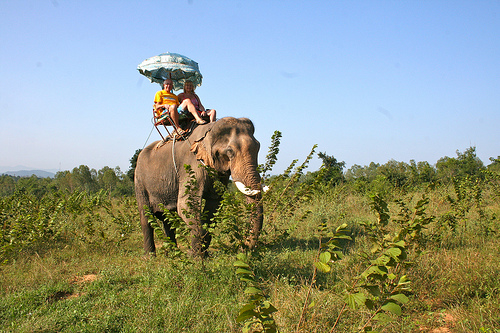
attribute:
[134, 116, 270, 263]
elephant — walking, grey, greyish, big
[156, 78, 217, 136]
couple — sitting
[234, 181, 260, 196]
tusk — white, large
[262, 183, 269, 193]
tusk — white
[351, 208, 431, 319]
plant — green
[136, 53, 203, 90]
umbrella — blue, shade, big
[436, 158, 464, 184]
tree — green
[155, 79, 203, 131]
man — smiling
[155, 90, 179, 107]
shirt — yellow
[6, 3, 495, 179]
sky — clear, blue, cloudless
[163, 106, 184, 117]
shorts — blue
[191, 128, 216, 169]
ear — big, flat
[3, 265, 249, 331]
grass — green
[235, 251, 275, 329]
weed — green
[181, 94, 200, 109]
shirt — red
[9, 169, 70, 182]
mountains — distant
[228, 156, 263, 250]
trunk — hanging, long